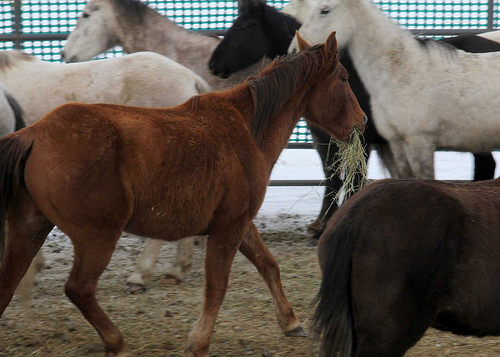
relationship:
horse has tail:
[0, 24, 369, 356] [1, 126, 35, 234]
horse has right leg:
[0, 24, 369, 356] [182, 188, 266, 354]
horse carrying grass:
[0, 24, 369, 356] [284, 130, 370, 230]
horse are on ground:
[0, 24, 369, 356] [6, 144, 499, 355]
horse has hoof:
[0, 24, 369, 356] [281, 325, 309, 341]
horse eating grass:
[0, 24, 369, 356] [284, 130, 370, 230]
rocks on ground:
[166, 309, 174, 318] [6, 144, 499, 355]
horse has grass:
[0, 24, 369, 356] [284, 130, 370, 230]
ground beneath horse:
[6, 144, 499, 355] [0, 24, 369, 356]